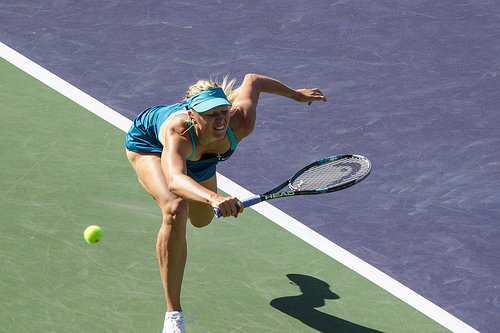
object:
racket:
[212, 152, 374, 216]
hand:
[210, 195, 244, 219]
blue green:
[0, 213, 296, 332]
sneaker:
[158, 307, 186, 332]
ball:
[81, 224, 105, 245]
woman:
[120, 71, 329, 332]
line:
[1, 40, 478, 332]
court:
[0, 0, 500, 332]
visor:
[185, 87, 233, 115]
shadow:
[268, 273, 387, 332]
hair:
[182, 75, 235, 110]